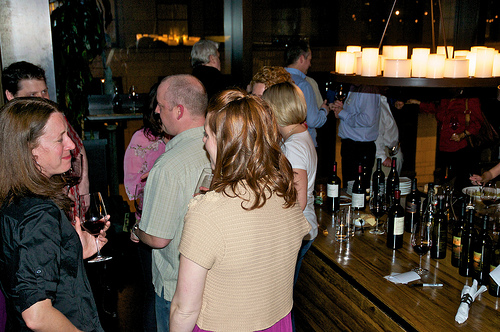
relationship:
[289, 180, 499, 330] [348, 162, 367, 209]
table covered with bottles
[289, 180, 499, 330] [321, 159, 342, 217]
table covered with beverage bottles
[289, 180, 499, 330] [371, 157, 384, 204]
table covered with bottles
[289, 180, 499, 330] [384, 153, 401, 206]
table covered with bottles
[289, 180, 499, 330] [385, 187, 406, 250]
table covered with wine bottle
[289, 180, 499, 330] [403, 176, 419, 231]
table covered with bottles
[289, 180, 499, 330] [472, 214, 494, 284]
table covered with bottles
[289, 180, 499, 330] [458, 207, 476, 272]
table covered with bottles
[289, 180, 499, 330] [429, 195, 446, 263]
table covered with bottles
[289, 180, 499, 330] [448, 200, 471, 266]
table covered with bottles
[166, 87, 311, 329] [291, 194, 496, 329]
woman near table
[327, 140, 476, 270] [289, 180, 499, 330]
beverage bottles on table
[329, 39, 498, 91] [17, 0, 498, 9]
lights hanging from ceiling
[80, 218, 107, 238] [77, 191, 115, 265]
red wine in glass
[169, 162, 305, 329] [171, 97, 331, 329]
sweater on woman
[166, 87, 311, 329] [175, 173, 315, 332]
woman in sweater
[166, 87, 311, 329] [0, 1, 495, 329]
woman in bar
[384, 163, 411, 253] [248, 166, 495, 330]
wine bottle on bar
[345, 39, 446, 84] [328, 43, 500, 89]
candles on lights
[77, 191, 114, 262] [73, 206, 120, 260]
glass in hand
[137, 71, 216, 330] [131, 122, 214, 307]
man in shirt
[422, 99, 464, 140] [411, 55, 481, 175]
shirt on person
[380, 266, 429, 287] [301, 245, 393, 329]
napkin sitting on bar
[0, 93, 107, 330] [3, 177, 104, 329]
lady with shirt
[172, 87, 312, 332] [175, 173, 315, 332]
woman with sweater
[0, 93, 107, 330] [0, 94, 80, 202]
lady with brown hair